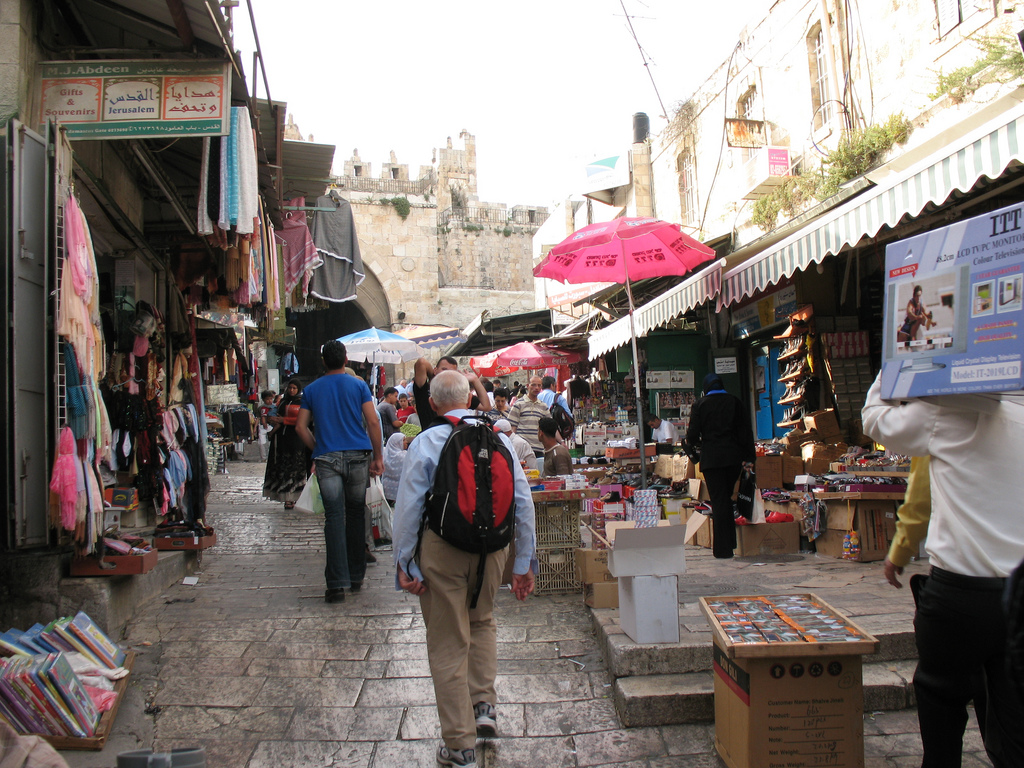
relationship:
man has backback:
[390, 367, 542, 767] [426, 413, 519, 553]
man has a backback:
[390, 367, 542, 767] [426, 413, 519, 553]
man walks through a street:
[390, 367, 542, 767] [53, 460, 991, 766]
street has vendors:
[53, 460, 991, 766] [1, 125, 1023, 763]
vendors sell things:
[1, 125, 1023, 763] [17, 57, 1021, 696]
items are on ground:
[6, 610, 133, 766] [55, 455, 1015, 766]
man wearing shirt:
[297, 339, 385, 604] [297, 372, 380, 449]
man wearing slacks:
[390, 367, 542, 767] [414, 528, 507, 751]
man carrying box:
[859, 367, 1023, 766] [880, 200, 1023, 401]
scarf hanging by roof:
[48, 427, 82, 533] [40, 0, 314, 324]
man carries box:
[859, 367, 1023, 766] [880, 200, 1023, 401]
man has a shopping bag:
[390, 367, 542, 767] [361, 469, 397, 552]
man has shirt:
[503, 375, 551, 479] [507, 393, 553, 453]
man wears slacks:
[390, 367, 542, 767] [414, 528, 507, 751]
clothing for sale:
[94, 295, 224, 555] [87, 219, 323, 563]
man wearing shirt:
[644, 411, 682, 452] [649, 417, 685, 447]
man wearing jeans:
[297, 339, 385, 604] [311, 451, 373, 595]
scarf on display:
[48, 427, 82, 533] [0, 181, 325, 499]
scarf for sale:
[48, 427, 82, 533] [87, 219, 323, 563]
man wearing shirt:
[503, 375, 551, 479] [507, 393, 553, 453]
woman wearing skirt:
[262, 381, 313, 511] [259, 413, 317, 504]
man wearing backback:
[390, 367, 542, 767] [426, 413, 519, 553]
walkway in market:
[53, 460, 991, 766] [0, 20, 1023, 756]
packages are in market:
[614, 482, 716, 681] [0, 20, 1023, 756]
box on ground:
[701, 591, 874, 766] [55, 455, 1015, 766]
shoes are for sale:
[765, 312, 834, 541] [87, 219, 323, 563]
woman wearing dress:
[262, 381, 313, 511] [259, 413, 317, 504]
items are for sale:
[6, 610, 133, 766] [87, 219, 323, 563]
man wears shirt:
[297, 339, 385, 604] [297, 372, 380, 449]